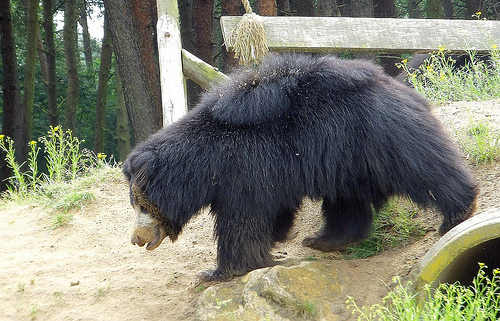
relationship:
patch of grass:
[61, 189, 96, 212] [31, 120, 455, 300]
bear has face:
[123, 53, 480, 280] [122, 154, 183, 249]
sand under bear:
[0, 196, 499, 320] [123, 53, 480, 280]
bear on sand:
[123, 53, 480, 280] [0, 196, 499, 320]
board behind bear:
[219, 14, 500, 50] [123, 53, 480, 280]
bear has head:
[123, 53, 480, 280] [122, 133, 214, 250]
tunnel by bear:
[418, 205, 499, 296] [123, 53, 480, 280]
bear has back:
[123, 53, 480, 280] [192, 59, 438, 155]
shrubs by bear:
[460, 121, 499, 163] [123, 53, 480, 280]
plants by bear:
[3, 126, 118, 224] [123, 53, 480, 280]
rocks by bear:
[198, 258, 334, 320] [123, 53, 480, 280]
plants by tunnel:
[376, 276, 499, 320] [418, 205, 499, 296]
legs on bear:
[208, 190, 284, 282] [123, 53, 480, 280]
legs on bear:
[305, 158, 477, 254] [123, 53, 480, 280]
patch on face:
[133, 200, 156, 226] [122, 154, 183, 249]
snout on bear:
[131, 212, 169, 251] [123, 53, 480, 280]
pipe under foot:
[418, 205, 499, 296] [429, 184, 484, 238]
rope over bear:
[227, 4, 272, 67] [123, 53, 480, 280]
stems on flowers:
[1, 147, 104, 186] [0, 127, 84, 149]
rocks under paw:
[198, 258, 334, 320] [300, 232, 357, 254]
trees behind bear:
[10, 9, 119, 144] [123, 53, 480, 280]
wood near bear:
[219, 14, 500, 50] [123, 53, 480, 280]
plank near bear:
[157, 4, 232, 122] [123, 53, 480, 280]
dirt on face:
[132, 186, 170, 225] [122, 154, 183, 249]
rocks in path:
[198, 258, 334, 320] [6, 98, 492, 316]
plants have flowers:
[3, 126, 118, 224] [0, 127, 84, 149]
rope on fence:
[227, 4, 272, 67] [155, 1, 498, 124]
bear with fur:
[123, 53, 480, 280] [205, 54, 382, 126]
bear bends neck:
[123, 53, 480, 280] [157, 122, 223, 215]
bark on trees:
[101, 0, 159, 142] [10, 9, 119, 144]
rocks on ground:
[198, 258, 334, 320] [6, 98, 492, 316]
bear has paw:
[123, 53, 480, 280] [300, 232, 357, 254]